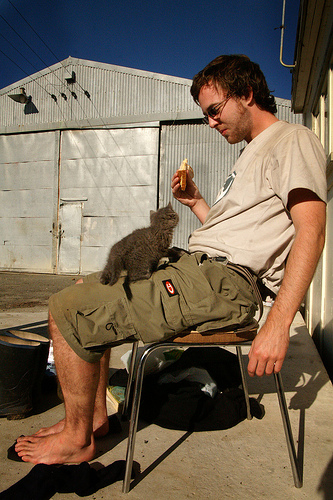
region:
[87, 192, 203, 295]
Kitty over lap of a person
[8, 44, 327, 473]
Man is sitting on a chair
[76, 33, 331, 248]
Man eats a sandwich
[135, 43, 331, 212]
Man wears glasses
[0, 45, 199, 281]
Building is grey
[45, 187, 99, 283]
Door of building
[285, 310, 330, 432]
Shadow cast on the ground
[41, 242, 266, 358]
Short is green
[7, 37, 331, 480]
Man has barefoot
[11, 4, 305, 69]
Sky is dark blue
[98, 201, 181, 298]
brown cat on man's lap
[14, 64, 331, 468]
sitting man, cat on lap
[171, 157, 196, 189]
sandwich in man's hand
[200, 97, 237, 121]
sunglasses on a man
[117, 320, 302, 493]
brown metal chair holding a man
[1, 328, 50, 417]
dark boot on the ground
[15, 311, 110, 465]
man's hairy leg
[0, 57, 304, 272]
large metal building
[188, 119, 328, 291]
man's tan shirt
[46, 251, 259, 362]
man's brown shorts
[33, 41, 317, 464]
person eating with a cat in his lap.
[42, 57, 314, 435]
person eating with an adorable cat in his lap.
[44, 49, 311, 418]
person eating with cute little cat in his lap.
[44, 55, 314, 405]
person eating with cat in his lap outside in daytime.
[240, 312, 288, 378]
left hand of a person.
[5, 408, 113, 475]
some bare feet of a person.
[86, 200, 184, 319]
cute little cat on person's lap.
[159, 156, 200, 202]
food in right hand of a person.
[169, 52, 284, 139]
person with dark colored hair.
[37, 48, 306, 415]
person wearing shirt and shorts.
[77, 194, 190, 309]
a young kitten sitting on a man's lap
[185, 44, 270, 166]
a man wearing glasses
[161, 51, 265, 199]
a man holding food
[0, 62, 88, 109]
electrical wires connected to a building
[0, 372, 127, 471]
a man with no shoes on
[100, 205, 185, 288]
a small grey kitten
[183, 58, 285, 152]
a man with brown hair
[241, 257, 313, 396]
a man's hand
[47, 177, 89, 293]
a door into a metal building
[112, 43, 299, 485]
a man sitting with a cat in his lap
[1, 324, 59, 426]
a pair of black boots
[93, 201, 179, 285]
a grey kitten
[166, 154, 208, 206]
a hand holding a partially eaten sandwich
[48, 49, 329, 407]
a man with a kitten on his lap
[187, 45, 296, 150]
the head of a man in glasses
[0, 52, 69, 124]
a light attached to a building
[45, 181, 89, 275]
the door to a building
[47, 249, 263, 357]
shorts length cargo pants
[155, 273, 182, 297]
clothing logo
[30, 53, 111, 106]
electrical wires attached to a building